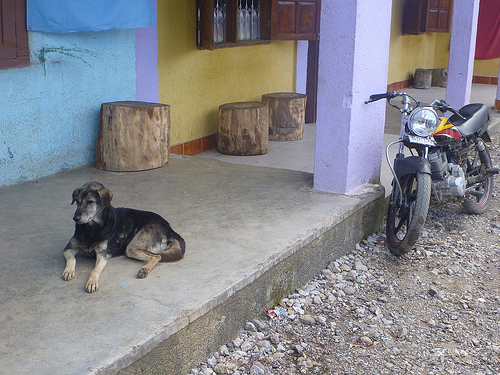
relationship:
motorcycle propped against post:
[358, 88, 491, 259] [309, 2, 386, 194]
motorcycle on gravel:
[358, 88, 491, 259] [362, 203, 482, 370]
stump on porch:
[260, 85, 308, 142] [2, 1, 497, 373]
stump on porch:
[214, 95, 271, 158] [2, 1, 497, 373]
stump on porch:
[99, 99, 171, 172] [2, 1, 497, 373]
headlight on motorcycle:
[405, 105, 440, 141] [358, 88, 491, 259]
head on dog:
[69, 183, 111, 225] [62, 181, 186, 293]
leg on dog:
[54, 253, 82, 284] [49, 162, 275, 334]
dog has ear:
[62, 181, 186, 293] [96, 187, 113, 208]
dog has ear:
[62, 181, 186, 293] [69, 184, 82, 208]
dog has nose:
[62, 181, 186, 293] [65, 206, 86, 226]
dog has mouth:
[62, 181, 186, 293] [71, 212, 96, 224]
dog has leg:
[38, 157, 194, 317] [72, 237, 107, 303]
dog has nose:
[62, 181, 186, 293] [63, 203, 89, 232]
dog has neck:
[62, 181, 186, 293] [69, 204, 120, 234]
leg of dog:
[83, 250, 110, 293] [62, 181, 186, 293]